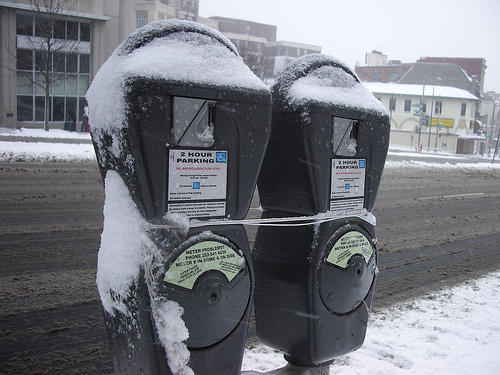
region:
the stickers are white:
[163, 143, 372, 229]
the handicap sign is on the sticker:
[211, 147, 233, 172]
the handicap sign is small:
[211, 145, 230, 172]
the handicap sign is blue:
[210, 148, 232, 172]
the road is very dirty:
[1, 136, 498, 373]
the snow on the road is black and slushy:
[1, 145, 497, 372]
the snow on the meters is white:
[74, 14, 389, 374]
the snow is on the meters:
[76, 13, 386, 373]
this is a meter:
[71, 9, 391, 374]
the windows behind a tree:
[11, 5, 100, 129]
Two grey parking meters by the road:
[89, 24, 409, 368]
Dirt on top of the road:
[6, 264, 92, 354]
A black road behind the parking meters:
[400, 245, 490, 280]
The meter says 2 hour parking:
[172, 149, 228, 173]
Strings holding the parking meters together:
[122, 209, 359, 239]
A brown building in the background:
[0, 9, 193, 138]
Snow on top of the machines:
[115, 24, 277, 98]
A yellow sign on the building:
[415, 111, 455, 130]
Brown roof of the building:
[370, 62, 480, 94]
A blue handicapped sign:
[216, 150, 229, 162]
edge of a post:
[289, 286, 323, 357]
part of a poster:
[321, 98, 381, 178]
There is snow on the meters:
[77, 29, 397, 348]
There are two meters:
[83, 40, 395, 372]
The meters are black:
[79, 36, 395, 350]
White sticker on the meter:
[164, 148, 242, 227]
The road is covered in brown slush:
[13, 130, 488, 350]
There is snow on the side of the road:
[329, 212, 489, 361]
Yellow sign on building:
[396, 107, 457, 141]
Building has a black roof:
[362, 44, 489, 158]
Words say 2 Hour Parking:
[169, 141, 229, 177]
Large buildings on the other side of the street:
[16, 43, 490, 163]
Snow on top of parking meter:
[119, 47, 247, 84]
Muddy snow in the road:
[410, 171, 495, 263]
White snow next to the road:
[441, 306, 494, 371]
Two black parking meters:
[98, 61, 365, 347]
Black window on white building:
[403, 97, 411, 112]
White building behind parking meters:
[396, 97, 473, 142]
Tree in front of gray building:
[37, 33, 63, 114]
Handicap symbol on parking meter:
[215, 151, 225, 163]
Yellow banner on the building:
[418, 114, 453, 128]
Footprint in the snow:
[373, 351, 420, 364]